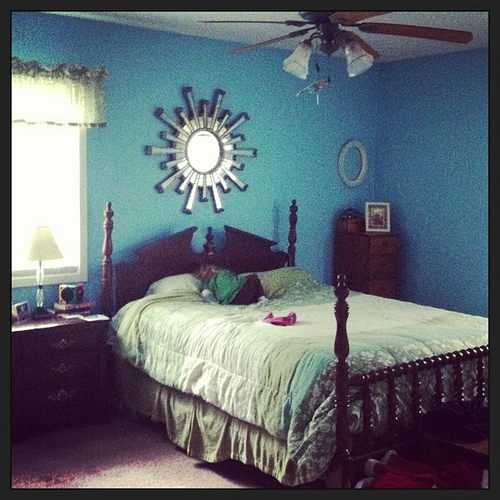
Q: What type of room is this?
A: It is a bedroom.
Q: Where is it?
A: This is at the bedroom.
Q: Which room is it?
A: It is a bedroom.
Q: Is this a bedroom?
A: Yes, it is a bedroom.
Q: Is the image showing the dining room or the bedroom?
A: It is showing the bedroom.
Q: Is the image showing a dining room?
A: No, the picture is showing a bedroom.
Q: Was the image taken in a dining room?
A: No, the picture was taken in a bedroom.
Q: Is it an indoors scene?
A: Yes, it is indoors.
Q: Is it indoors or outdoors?
A: It is indoors.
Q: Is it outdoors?
A: No, it is indoors.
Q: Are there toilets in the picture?
A: No, there are no toilets.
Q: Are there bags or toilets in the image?
A: No, there are no toilets or bags.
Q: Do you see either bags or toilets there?
A: No, there are no toilets or bags.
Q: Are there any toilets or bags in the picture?
A: No, there are no toilets or bags.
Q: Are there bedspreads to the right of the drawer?
A: Yes, there is a bedspread to the right of the drawer.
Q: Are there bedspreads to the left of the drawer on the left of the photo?
A: No, the bedspread is to the right of the drawer.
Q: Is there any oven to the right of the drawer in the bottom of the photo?
A: No, there is a bedspread to the right of the drawer.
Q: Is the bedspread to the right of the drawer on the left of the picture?
A: Yes, the bedspread is to the right of the drawer.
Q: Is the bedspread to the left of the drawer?
A: No, the bedspread is to the right of the drawer.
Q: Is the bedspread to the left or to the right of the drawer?
A: The bedspread is to the right of the drawer.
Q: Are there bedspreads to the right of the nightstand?
A: Yes, there is a bedspread to the right of the nightstand.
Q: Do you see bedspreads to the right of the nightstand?
A: Yes, there is a bedspread to the right of the nightstand.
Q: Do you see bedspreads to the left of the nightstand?
A: No, the bedspread is to the right of the nightstand.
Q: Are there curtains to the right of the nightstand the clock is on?
A: No, there is a bedspread to the right of the nightstand.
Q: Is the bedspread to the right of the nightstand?
A: Yes, the bedspread is to the right of the nightstand.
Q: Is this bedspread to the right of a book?
A: No, the bedspread is to the right of the nightstand.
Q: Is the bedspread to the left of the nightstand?
A: No, the bedspread is to the right of the nightstand.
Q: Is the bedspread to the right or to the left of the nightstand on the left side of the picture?
A: The bedspread is to the right of the nightstand.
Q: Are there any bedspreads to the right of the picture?
A: Yes, there is a bedspread to the right of the picture.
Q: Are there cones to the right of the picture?
A: No, there is a bedspread to the right of the picture.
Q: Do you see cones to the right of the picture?
A: No, there is a bedspread to the right of the picture.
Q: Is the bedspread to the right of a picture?
A: Yes, the bedspread is to the right of a picture.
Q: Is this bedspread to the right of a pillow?
A: No, the bedspread is to the right of a picture.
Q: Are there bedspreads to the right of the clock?
A: Yes, there is a bedspread to the right of the clock.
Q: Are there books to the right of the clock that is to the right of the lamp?
A: No, there is a bedspread to the right of the clock.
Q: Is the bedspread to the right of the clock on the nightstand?
A: Yes, the bedspread is to the right of the clock.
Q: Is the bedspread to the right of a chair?
A: No, the bedspread is to the right of the clock.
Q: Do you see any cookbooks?
A: No, there are no cookbooks.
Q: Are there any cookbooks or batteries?
A: No, there are no cookbooks or batteries.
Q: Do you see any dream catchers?
A: No, there are no dream catchers.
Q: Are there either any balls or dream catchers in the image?
A: No, there are no dream catchers or balls.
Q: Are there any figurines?
A: No, there are no figurines.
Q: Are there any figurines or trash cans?
A: No, there are no figurines or trash cans.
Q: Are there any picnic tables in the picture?
A: No, there are no picnic tables.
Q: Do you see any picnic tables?
A: No, there are no picnic tables.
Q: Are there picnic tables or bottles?
A: No, there are no picnic tables or bottles.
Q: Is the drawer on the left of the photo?
A: Yes, the drawer is on the left of the image.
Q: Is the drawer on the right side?
A: No, the drawer is on the left of the image.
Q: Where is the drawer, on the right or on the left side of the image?
A: The drawer is on the left of the image.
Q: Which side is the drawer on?
A: The drawer is on the left of the image.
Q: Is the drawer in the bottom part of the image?
A: Yes, the drawer is in the bottom of the image.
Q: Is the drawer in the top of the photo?
A: No, the drawer is in the bottom of the image.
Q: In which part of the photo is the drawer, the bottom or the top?
A: The drawer is in the bottom of the image.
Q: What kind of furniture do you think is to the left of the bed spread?
A: The piece of furniture is a drawer.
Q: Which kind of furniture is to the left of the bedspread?
A: The piece of furniture is a drawer.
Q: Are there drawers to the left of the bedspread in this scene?
A: Yes, there is a drawer to the left of the bedspread.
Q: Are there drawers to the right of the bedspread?
A: No, the drawer is to the left of the bedspread.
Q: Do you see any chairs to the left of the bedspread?
A: No, there is a drawer to the left of the bedspread.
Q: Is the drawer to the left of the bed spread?
A: Yes, the drawer is to the left of the bed spread.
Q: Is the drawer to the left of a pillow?
A: No, the drawer is to the left of the bed spread.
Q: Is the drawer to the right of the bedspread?
A: No, the drawer is to the left of the bedspread.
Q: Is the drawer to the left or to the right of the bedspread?
A: The drawer is to the left of the bedspread.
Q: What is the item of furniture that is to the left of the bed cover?
A: The piece of furniture is a drawer.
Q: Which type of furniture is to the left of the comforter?
A: The piece of furniture is a drawer.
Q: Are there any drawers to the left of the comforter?
A: Yes, there is a drawer to the left of the comforter.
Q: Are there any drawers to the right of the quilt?
A: No, the drawer is to the left of the quilt.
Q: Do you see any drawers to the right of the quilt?
A: No, the drawer is to the left of the quilt.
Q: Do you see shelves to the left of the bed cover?
A: No, there is a drawer to the left of the bed cover.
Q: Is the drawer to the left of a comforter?
A: Yes, the drawer is to the left of a comforter.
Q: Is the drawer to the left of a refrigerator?
A: No, the drawer is to the left of a comforter.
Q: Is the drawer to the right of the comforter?
A: No, the drawer is to the left of the comforter.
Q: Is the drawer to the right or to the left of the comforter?
A: The drawer is to the left of the comforter.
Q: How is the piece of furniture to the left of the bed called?
A: The piece of furniture is a drawer.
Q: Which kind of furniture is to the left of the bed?
A: The piece of furniture is a drawer.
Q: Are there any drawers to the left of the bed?
A: Yes, there is a drawer to the left of the bed.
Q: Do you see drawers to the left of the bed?
A: Yes, there is a drawer to the left of the bed.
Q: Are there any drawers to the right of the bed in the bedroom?
A: No, the drawer is to the left of the bed.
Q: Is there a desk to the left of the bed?
A: No, there is a drawer to the left of the bed.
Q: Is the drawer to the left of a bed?
A: Yes, the drawer is to the left of a bed.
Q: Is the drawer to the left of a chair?
A: No, the drawer is to the left of a bed.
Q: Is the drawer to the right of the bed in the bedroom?
A: No, the drawer is to the left of the bed.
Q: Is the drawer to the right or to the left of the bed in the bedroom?
A: The drawer is to the left of the bed.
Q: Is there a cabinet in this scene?
A: Yes, there is a cabinet.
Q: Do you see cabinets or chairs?
A: Yes, there is a cabinet.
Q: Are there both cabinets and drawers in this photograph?
A: Yes, there are both a cabinet and drawers.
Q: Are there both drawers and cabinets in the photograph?
A: Yes, there are both a cabinet and drawers.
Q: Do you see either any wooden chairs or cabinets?
A: Yes, there is a wood cabinet.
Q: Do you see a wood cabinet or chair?
A: Yes, there is a wood cabinet.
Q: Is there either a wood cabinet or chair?
A: Yes, there is a wood cabinet.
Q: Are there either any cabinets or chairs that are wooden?
A: Yes, the cabinet is wooden.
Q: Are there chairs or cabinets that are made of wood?
A: Yes, the cabinet is made of wood.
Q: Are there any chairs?
A: No, there are no chairs.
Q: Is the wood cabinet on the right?
A: Yes, the cabinet is on the right of the image.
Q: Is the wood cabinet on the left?
A: No, the cabinet is on the right of the image.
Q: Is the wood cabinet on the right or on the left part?
A: The cabinet is on the right of the image.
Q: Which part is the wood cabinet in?
A: The cabinet is on the right of the image.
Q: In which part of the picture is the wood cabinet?
A: The cabinet is on the right of the image.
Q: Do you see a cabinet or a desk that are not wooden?
A: No, there is a cabinet but it is wooden.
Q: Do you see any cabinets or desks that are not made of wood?
A: No, there is a cabinet but it is made of wood.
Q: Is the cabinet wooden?
A: Yes, the cabinet is wooden.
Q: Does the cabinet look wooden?
A: Yes, the cabinet is wooden.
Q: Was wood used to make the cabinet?
A: Yes, the cabinet is made of wood.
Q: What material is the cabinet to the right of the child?
A: The cabinet is made of wood.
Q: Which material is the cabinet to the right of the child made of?
A: The cabinet is made of wood.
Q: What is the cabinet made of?
A: The cabinet is made of wood.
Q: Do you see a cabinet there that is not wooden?
A: No, there is a cabinet but it is wooden.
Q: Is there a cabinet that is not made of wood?
A: No, there is a cabinet but it is made of wood.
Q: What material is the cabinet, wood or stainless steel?
A: The cabinet is made of wood.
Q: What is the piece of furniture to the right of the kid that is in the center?
A: The piece of furniture is a cabinet.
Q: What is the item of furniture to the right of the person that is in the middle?
A: The piece of furniture is a cabinet.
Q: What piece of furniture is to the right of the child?
A: The piece of furniture is a cabinet.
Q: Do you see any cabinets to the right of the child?
A: Yes, there is a cabinet to the right of the child.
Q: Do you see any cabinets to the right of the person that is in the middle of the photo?
A: Yes, there is a cabinet to the right of the child.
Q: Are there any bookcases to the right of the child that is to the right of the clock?
A: No, there is a cabinet to the right of the child.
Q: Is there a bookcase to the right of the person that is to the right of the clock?
A: No, there is a cabinet to the right of the child.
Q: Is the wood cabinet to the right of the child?
A: Yes, the cabinet is to the right of the child.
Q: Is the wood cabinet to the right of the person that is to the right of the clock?
A: Yes, the cabinet is to the right of the child.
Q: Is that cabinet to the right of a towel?
A: No, the cabinet is to the right of the child.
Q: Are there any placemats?
A: No, there are no placemats.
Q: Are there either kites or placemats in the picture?
A: No, there are no placemats or kites.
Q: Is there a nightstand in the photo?
A: Yes, there is a nightstand.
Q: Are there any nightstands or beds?
A: Yes, there is a nightstand.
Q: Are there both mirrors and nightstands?
A: Yes, there are both a nightstand and a mirror.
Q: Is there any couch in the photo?
A: No, there are no couches.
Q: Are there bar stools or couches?
A: No, there are no couches or bar stools.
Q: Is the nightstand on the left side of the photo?
A: Yes, the nightstand is on the left of the image.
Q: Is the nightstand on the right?
A: No, the nightstand is on the left of the image.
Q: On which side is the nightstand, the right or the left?
A: The nightstand is on the left of the image.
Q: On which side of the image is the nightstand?
A: The nightstand is on the left of the image.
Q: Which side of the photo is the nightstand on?
A: The nightstand is on the left of the image.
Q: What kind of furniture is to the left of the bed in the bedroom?
A: The piece of furniture is a nightstand.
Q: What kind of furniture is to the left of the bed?
A: The piece of furniture is a nightstand.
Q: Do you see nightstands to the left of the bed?
A: Yes, there is a nightstand to the left of the bed.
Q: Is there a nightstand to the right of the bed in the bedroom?
A: No, the nightstand is to the left of the bed.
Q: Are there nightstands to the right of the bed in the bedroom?
A: No, the nightstand is to the left of the bed.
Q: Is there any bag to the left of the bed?
A: No, there is a nightstand to the left of the bed.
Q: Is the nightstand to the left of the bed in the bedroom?
A: Yes, the nightstand is to the left of the bed.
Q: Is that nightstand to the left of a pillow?
A: No, the nightstand is to the left of the bed.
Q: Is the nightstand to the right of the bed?
A: No, the nightstand is to the left of the bed.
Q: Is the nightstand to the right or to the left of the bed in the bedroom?
A: The nightstand is to the left of the bed.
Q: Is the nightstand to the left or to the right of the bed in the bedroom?
A: The nightstand is to the left of the bed.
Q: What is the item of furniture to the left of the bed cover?
A: The piece of furniture is a nightstand.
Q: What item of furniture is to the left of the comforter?
A: The piece of furniture is a nightstand.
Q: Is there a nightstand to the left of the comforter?
A: Yes, there is a nightstand to the left of the comforter.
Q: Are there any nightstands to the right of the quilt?
A: No, the nightstand is to the left of the quilt.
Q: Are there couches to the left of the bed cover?
A: No, there is a nightstand to the left of the bed cover.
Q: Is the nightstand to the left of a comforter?
A: Yes, the nightstand is to the left of a comforter.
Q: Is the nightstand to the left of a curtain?
A: No, the nightstand is to the left of a comforter.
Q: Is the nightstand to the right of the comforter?
A: No, the nightstand is to the left of the comforter.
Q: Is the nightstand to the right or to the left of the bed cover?
A: The nightstand is to the left of the bed cover.